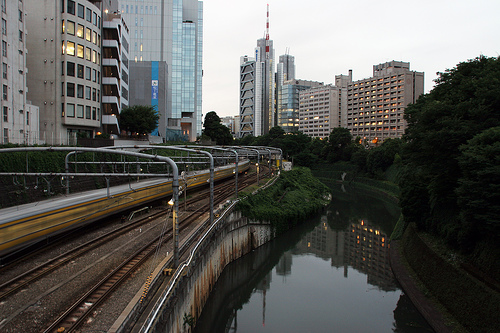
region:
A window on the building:
[61, 103, 74, 119]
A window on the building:
[75, 103, 85, 119]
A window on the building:
[64, 81, 76, 97]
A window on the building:
[74, 83, 85, 100]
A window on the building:
[65, 59, 77, 77]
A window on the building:
[76, 60, 85, 77]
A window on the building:
[60, 38, 75, 55]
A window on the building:
[75, 42, 87, 59]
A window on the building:
[60, 18, 74, 36]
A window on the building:
[75, 19, 85, 37]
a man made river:
[198, 242, 405, 331]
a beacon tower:
[263, 5, 272, 46]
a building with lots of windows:
[347, 65, 425, 145]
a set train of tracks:
[13, 169, 267, 330]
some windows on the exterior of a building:
[183, 19, 193, 114]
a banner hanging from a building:
[148, 55, 163, 137]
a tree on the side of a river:
[409, 68, 499, 247]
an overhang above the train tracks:
[2, 145, 183, 265]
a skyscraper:
[257, 40, 277, 136]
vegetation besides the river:
[293, 131, 405, 181]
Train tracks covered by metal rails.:
[1, 143, 291, 330]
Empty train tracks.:
[1, 163, 274, 332]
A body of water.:
[182, 172, 458, 332]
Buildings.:
[229, 2, 426, 152]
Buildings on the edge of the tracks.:
[2, 0, 202, 147]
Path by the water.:
[317, 167, 498, 331]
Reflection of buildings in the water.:
[233, 204, 399, 331]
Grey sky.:
[202, 3, 497, 126]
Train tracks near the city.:
[1, 155, 278, 331]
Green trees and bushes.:
[201, 53, 498, 284]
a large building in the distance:
[242, 15, 302, 148]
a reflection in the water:
[290, 187, 411, 295]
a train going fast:
[3, 158, 251, 258]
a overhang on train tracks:
[18, 139, 188, 272]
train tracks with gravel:
[3, 230, 135, 329]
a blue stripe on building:
[128, 49, 175, 145]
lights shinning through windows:
[43, 8, 103, 71]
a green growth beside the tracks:
[221, 160, 323, 247]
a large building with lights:
[340, 62, 410, 149]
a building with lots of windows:
[152, 3, 221, 135]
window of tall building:
[139, 32, 156, 52]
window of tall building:
[285, 100, 293, 113]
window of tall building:
[380, 105, 395, 120]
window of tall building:
[360, 92, 373, 102]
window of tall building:
[303, 95, 328, 115]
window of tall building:
[176, 43, 188, 66]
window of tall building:
[63, 60, 85, 89]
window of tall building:
[59, 36, 73, 55]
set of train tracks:
[56, 250, 148, 324]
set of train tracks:
[14, 228, 96, 293]